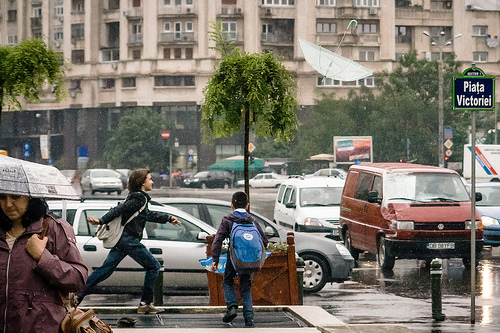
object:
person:
[75, 165, 184, 316]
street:
[351, 271, 491, 333]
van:
[336, 160, 484, 272]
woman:
[0, 206, 95, 333]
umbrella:
[0, 155, 85, 203]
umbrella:
[294, 18, 375, 85]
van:
[272, 177, 348, 234]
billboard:
[333, 135, 374, 165]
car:
[182, 169, 232, 189]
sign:
[160, 130, 170, 140]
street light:
[423, 29, 458, 169]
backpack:
[229, 221, 268, 275]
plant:
[268, 240, 288, 255]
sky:
[226, 19, 499, 75]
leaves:
[218, 79, 241, 97]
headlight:
[396, 220, 415, 229]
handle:
[148, 247, 162, 254]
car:
[42, 196, 299, 296]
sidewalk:
[99, 310, 284, 333]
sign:
[451, 66, 496, 111]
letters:
[464, 80, 485, 94]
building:
[0, 0, 500, 177]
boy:
[210, 191, 269, 328]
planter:
[205, 230, 302, 305]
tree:
[196, 17, 303, 214]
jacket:
[97, 190, 172, 242]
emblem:
[243, 233, 254, 241]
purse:
[52, 287, 120, 332]